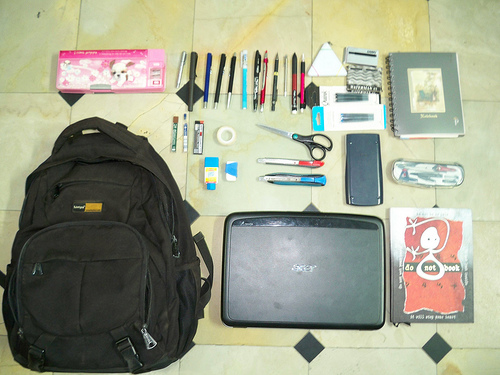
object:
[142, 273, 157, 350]
zipper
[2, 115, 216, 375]
backpack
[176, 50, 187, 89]
pens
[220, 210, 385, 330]
laptop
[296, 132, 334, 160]
handles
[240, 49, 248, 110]
pen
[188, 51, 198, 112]
pen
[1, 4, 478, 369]
table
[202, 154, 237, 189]
eraser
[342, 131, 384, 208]
calculator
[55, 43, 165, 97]
geometry set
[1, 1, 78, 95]
tile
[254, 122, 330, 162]
scissors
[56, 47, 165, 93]
box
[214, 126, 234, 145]
tape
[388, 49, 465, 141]
notebook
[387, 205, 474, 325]
book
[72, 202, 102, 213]
logo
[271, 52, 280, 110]
pencil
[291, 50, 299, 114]
marker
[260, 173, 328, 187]
white out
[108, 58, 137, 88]
puppy